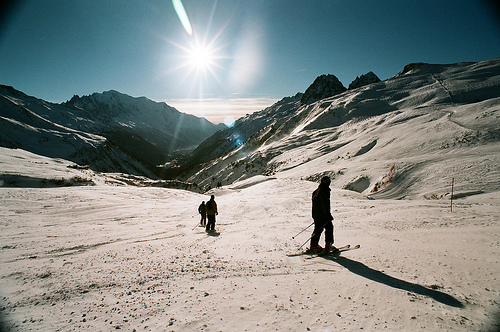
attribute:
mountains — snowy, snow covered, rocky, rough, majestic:
[0, 58, 499, 331]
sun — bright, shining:
[175, 25, 217, 82]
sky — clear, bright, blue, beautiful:
[3, 3, 498, 127]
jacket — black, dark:
[311, 188, 331, 222]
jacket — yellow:
[205, 202, 217, 215]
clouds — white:
[179, 91, 276, 131]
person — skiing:
[198, 197, 207, 226]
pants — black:
[310, 220, 334, 245]